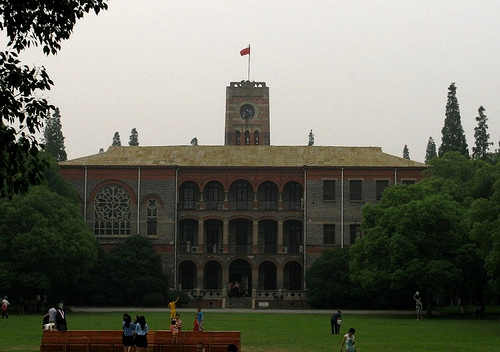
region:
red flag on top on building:
[220, 33, 294, 105]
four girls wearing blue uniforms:
[114, 306, 159, 349]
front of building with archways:
[169, 167, 328, 319]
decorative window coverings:
[84, 167, 146, 244]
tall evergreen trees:
[412, 81, 499, 185]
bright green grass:
[240, 299, 440, 349]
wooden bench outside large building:
[32, 319, 265, 346]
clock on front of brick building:
[228, 93, 271, 128]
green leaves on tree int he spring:
[348, 176, 497, 331]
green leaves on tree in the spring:
[3, 103, 87, 298]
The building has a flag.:
[225, 33, 265, 80]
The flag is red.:
[222, 39, 274, 84]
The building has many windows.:
[165, 171, 399, 295]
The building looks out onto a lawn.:
[0, 282, 496, 349]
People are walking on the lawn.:
[17, 290, 427, 350]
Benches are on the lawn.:
[37, 315, 256, 350]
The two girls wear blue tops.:
[118, 309, 154, 336]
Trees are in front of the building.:
[326, 142, 498, 317]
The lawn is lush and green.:
[0, 308, 497, 350]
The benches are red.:
[32, 322, 248, 350]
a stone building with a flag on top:
[53, 41, 428, 307]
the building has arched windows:
[65, 165, 310, 300]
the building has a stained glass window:
[73, 142, 146, 252]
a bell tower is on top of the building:
[218, 41, 273, 186]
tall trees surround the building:
[5, 91, 496, 314]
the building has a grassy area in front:
[3, 273, 496, 348]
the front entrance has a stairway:
[217, 255, 253, 312]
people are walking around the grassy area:
[6, 276, 496, 347]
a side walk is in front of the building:
[25, 301, 458, 313]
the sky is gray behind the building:
[12, 1, 499, 166]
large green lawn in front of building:
[0, 295, 499, 346]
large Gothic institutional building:
[59, 65, 434, 312]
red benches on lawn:
[31, 327, 251, 347]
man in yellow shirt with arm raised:
[167, 291, 182, 321]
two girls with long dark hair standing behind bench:
[118, 310, 155, 348]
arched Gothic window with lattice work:
[88, 177, 138, 240]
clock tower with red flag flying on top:
[221, 39, 271, 143]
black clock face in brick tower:
[236, 99, 261, 125]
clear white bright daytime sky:
[0, 0, 499, 166]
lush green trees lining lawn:
[1, 0, 498, 319]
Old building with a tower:
[36, 28, 480, 318]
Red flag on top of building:
[236, 40, 258, 82]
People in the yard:
[0, 291, 495, 349]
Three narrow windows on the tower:
[230, 126, 265, 148]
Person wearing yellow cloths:
[162, 291, 183, 321]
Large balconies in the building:
[172, 183, 309, 273]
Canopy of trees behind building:
[96, 125, 324, 148]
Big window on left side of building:
[79, 176, 142, 243]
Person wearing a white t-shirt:
[330, 325, 360, 350]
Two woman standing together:
[118, 313, 157, 350]